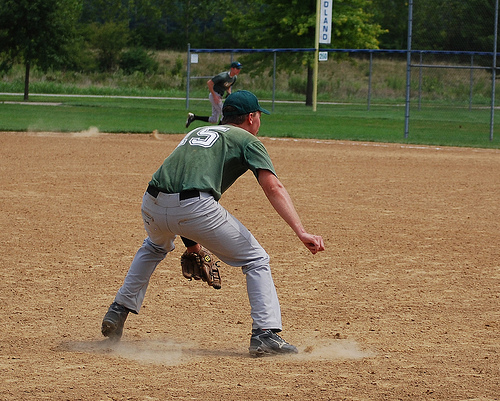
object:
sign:
[315, 47, 331, 67]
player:
[81, 75, 343, 370]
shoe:
[91, 297, 137, 352]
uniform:
[178, 58, 249, 133]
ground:
[365, 157, 396, 192]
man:
[177, 52, 258, 132]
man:
[82, 81, 340, 367]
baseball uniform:
[89, 83, 316, 359]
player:
[174, 57, 250, 137]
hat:
[209, 83, 277, 129]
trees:
[212, 1, 396, 112]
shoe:
[237, 321, 305, 365]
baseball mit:
[173, 239, 232, 295]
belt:
[134, 177, 209, 206]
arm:
[242, 136, 307, 241]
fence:
[178, 31, 499, 150]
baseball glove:
[171, 241, 231, 295]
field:
[0, 78, 485, 141]